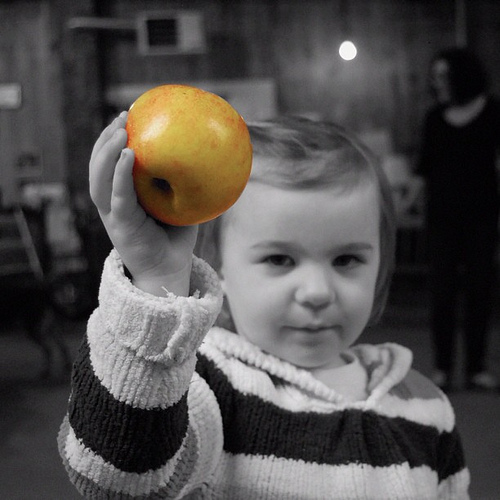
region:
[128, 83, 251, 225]
an apple in a girl's hand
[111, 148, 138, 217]
pinky finger of a young girl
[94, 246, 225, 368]
cuff of a sweater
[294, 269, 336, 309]
nose of a girl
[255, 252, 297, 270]
a girl's right eye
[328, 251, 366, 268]
a girl's left eye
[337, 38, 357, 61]
a lightbulb in the background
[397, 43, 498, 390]
a woman standing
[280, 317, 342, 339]
mouth of a child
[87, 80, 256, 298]
apple in a girl's hand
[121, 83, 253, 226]
Large round red and orange apple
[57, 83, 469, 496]
Small child with blonde hair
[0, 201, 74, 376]
Large wooden curved chair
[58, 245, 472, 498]
Small black and white sweater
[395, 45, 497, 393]
Tall woman with dark hair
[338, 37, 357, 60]
Small bright round light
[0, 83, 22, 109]
Small square white plastic box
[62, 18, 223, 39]
Long high wooden shelf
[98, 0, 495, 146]
Large wide wooden wall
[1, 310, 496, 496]
Large wide carpeted floor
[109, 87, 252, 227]
apple in right handd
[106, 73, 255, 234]
apple in hand is red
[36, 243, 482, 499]
little girl wearing sweater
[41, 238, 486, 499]
sweater is multi colored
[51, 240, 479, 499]
little girl sweater is striped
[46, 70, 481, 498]
little girl holding an apple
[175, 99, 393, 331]
little girl has short hair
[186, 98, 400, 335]
little girl has brown hair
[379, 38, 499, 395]
woman standing in background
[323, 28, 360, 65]
light shining on back wall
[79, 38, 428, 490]
a child holding an apple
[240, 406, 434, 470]
a dark stripe on a sweater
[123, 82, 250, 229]
a delicious red apple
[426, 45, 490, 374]
a woman wearing a black shirt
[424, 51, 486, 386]
a woman wearing black pants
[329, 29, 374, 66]
a light bulb shining overhead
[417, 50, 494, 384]
a woman standing behind the child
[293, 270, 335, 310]
a nose on a face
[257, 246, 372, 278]
two small dark eyes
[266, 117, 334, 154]
soft hair on a head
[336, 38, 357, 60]
light bulb hanging from a ceiling and shining bright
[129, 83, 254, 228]
yellow and reddish apple being held up by a young girl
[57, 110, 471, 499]
young child posing with an apple held up in her right hand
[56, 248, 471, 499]
soft stripped sweater with small knitting worn by a young child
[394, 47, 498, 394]
adult woman with dark clothes standing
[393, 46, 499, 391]
woman with dark hair and black shoes standing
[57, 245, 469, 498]
sweater with stripes worn by a young child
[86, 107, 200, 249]
child's hand holding onto an apple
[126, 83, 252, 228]
fresh apple being held by a child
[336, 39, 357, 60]
light bulb turned on and attached to a fixture hanging from the ceiling